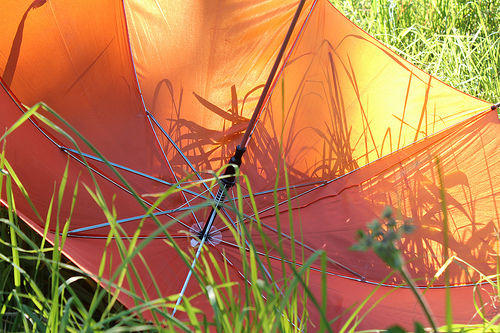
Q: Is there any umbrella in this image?
A: Yes, there is an umbrella.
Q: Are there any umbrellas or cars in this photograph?
A: Yes, there is an umbrella.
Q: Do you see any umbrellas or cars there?
A: Yes, there is an umbrella.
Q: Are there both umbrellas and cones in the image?
A: No, there is an umbrella but no cones.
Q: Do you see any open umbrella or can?
A: Yes, there is an open umbrella.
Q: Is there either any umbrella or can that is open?
A: Yes, the umbrella is open.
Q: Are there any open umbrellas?
A: Yes, there is an open umbrella.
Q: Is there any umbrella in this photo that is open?
A: Yes, there is an umbrella that is open.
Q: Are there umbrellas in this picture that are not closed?
A: Yes, there is a open umbrella.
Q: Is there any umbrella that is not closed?
A: Yes, there is a open umbrella.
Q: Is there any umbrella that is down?
A: Yes, there is an umbrella that is down.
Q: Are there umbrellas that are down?
A: Yes, there is an umbrella that is down.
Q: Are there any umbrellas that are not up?
A: Yes, there is an umbrella that is down.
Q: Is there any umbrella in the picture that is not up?
A: Yes, there is an umbrella that is down.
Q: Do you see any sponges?
A: No, there are no sponges.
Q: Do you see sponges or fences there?
A: No, there are no sponges or fences.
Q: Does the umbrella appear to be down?
A: Yes, the umbrella is down.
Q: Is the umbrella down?
A: Yes, the umbrella is down.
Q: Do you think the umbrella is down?
A: Yes, the umbrella is down.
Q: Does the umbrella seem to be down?
A: Yes, the umbrella is down.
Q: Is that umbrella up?
A: No, the umbrella is down.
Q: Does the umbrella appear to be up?
A: No, the umbrella is down.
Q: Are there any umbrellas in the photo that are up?
A: No, there is an umbrella but it is down.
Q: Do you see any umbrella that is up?
A: No, there is an umbrella but it is down.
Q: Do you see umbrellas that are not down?
A: No, there is an umbrella but it is down.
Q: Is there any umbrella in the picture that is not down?
A: No, there is an umbrella but it is down.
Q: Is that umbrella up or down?
A: The umbrella is down.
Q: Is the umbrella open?
A: Yes, the umbrella is open.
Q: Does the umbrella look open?
A: Yes, the umbrella is open.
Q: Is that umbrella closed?
A: No, the umbrella is open.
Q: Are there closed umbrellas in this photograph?
A: No, there is an umbrella but it is open.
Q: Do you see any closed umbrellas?
A: No, there is an umbrella but it is open.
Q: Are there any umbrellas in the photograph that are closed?
A: No, there is an umbrella but it is open.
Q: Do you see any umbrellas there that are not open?
A: No, there is an umbrella but it is open.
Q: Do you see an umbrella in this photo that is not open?
A: No, there is an umbrella but it is open.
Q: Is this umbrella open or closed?
A: The umbrella is open.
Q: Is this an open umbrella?
A: Yes, this is an open umbrella.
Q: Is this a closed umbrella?
A: No, this is an open umbrella.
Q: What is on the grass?
A: The umbrella is on the grass.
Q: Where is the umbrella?
A: The umbrella is on the grass.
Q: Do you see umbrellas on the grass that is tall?
A: Yes, there is an umbrella on the grass.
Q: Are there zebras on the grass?
A: No, there is an umbrella on the grass.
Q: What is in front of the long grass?
A: The umbrella is in front of the grass.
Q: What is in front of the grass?
A: The umbrella is in front of the grass.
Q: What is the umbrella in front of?
A: The umbrella is in front of the grass.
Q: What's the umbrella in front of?
A: The umbrella is in front of the grass.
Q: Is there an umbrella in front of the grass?
A: Yes, there is an umbrella in front of the grass.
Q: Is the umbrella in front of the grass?
A: Yes, the umbrella is in front of the grass.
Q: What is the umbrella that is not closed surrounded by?
A: The umbrella is surrounded by the grass.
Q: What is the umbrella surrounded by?
A: The umbrella is surrounded by the grass.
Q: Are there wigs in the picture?
A: No, there are no wigs.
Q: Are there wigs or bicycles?
A: No, there are no wigs or bicycles.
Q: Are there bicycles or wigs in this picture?
A: No, there are no wigs or bicycles.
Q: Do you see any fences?
A: No, there are no fences.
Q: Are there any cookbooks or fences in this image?
A: No, there are no fences or cookbooks.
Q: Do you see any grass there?
A: Yes, there is grass.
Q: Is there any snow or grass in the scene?
A: Yes, there is grass.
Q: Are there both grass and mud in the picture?
A: No, there is grass but no mud.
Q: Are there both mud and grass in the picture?
A: No, there is grass but no mud.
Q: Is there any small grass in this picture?
A: Yes, there is small grass.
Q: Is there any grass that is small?
A: Yes, there is grass that is small.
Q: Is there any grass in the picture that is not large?
A: Yes, there is small grass.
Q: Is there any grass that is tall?
A: Yes, there is tall grass.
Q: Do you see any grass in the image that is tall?
A: Yes, there is grass that is tall.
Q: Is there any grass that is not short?
A: Yes, there is tall grass.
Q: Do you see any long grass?
A: Yes, there is long grass.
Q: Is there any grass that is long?
A: Yes, there is grass that is long.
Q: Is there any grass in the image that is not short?
A: Yes, there is long grass.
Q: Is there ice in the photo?
A: No, there is no ice.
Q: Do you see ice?
A: No, there is no ice.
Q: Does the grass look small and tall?
A: Yes, the grass is small and tall.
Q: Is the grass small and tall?
A: Yes, the grass is small and tall.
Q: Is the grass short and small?
A: No, the grass is small but tall.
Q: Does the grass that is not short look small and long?
A: Yes, the grass is small and long.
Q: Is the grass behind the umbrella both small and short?
A: No, the grass is small but long.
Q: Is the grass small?
A: Yes, the grass is small.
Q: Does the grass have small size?
A: Yes, the grass is small.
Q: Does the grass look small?
A: Yes, the grass is small.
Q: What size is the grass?
A: The grass is small.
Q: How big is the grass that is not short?
A: The grass is small.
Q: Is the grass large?
A: No, the grass is small.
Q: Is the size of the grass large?
A: No, the grass is small.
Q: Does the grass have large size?
A: No, the grass is small.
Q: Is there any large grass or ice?
A: No, there is grass but it is small.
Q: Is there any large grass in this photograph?
A: No, there is grass but it is small.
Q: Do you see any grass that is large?
A: No, there is grass but it is small.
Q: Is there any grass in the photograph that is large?
A: No, there is grass but it is small.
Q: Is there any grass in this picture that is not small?
A: No, there is grass but it is small.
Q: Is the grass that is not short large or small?
A: The grass is small.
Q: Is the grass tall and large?
A: No, the grass is tall but small.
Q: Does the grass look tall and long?
A: Yes, the grass is tall and long.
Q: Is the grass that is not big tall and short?
A: No, the grass is tall but long.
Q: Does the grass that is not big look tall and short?
A: No, the grass is tall but long.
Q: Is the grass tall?
A: Yes, the grass is tall.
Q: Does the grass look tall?
A: Yes, the grass is tall.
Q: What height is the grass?
A: The grass is tall.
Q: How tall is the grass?
A: The grass is tall.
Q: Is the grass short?
A: No, the grass is tall.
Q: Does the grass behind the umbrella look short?
A: No, the grass is tall.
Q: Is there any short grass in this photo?
A: No, there is grass but it is tall.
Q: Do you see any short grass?
A: No, there is grass but it is tall.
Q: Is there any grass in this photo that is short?
A: No, there is grass but it is tall.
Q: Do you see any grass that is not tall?
A: No, there is grass but it is tall.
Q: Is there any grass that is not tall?
A: No, there is grass but it is tall.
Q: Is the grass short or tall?
A: The grass is tall.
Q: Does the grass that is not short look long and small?
A: Yes, the grass is long and small.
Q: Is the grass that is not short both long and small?
A: Yes, the grass is long and small.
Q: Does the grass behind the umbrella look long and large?
A: No, the grass is long but small.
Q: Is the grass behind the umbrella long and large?
A: No, the grass is long but small.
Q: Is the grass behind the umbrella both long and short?
A: No, the grass is long but tall.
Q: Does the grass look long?
A: Yes, the grass is long.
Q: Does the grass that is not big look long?
A: Yes, the grass is long.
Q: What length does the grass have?
A: The grass has long length.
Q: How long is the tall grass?
A: The grass is long.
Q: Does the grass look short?
A: No, the grass is long.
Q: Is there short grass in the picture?
A: No, there is grass but it is long.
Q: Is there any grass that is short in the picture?
A: No, there is grass but it is long.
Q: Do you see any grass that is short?
A: No, there is grass but it is long.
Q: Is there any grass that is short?
A: No, there is grass but it is long.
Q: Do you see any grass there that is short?
A: No, there is grass but it is long.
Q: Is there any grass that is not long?
A: No, there is grass but it is long.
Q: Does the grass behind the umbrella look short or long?
A: The grass is long.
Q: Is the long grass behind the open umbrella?
A: Yes, the grass is behind the umbrella.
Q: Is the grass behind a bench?
A: No, the grass is behind the umbrella.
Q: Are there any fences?
A: No, there are no fences.